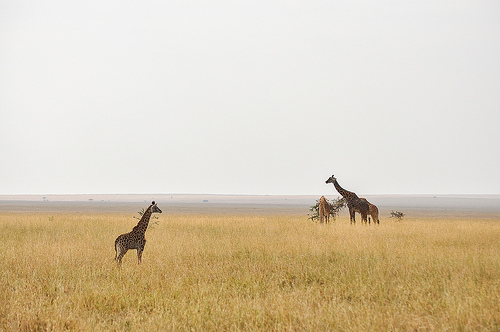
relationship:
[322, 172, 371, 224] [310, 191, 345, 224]
giraffe by a tree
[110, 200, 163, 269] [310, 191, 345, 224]
baby by tree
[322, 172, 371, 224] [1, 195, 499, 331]
giraffe in grassland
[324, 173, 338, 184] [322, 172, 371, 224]
head on giraffe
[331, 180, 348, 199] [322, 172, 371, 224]
neck on giraffe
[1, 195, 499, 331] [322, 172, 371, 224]
grassland with a giraffe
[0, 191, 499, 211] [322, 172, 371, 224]
horizon with giraffe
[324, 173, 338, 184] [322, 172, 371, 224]
head of giraffe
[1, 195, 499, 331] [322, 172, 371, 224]
grassland with giraffe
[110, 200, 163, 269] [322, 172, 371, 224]
baby with giraffe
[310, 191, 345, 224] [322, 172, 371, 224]
tree with giraffe